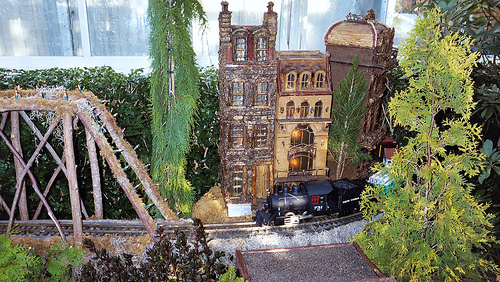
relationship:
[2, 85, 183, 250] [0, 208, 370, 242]
structure over tracks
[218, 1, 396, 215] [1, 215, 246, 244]
building by tracks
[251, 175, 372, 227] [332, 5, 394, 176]
model train in front of model building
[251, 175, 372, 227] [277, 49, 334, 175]
model train in front of model building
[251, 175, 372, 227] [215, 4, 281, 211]
model train in front of model building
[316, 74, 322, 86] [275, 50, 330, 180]
window on side of house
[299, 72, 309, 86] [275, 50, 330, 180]
window on side of house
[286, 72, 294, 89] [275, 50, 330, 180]
window on side of house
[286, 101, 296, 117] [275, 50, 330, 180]
window on side of house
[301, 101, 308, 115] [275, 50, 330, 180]
window on side of house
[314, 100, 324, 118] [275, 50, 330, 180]
window on side of house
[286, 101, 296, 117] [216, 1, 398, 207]
window on side of house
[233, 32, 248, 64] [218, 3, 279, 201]
window on side of house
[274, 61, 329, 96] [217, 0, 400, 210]
windows in mansion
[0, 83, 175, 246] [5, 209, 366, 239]
bridge over tracks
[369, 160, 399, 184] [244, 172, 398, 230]
pipes in train